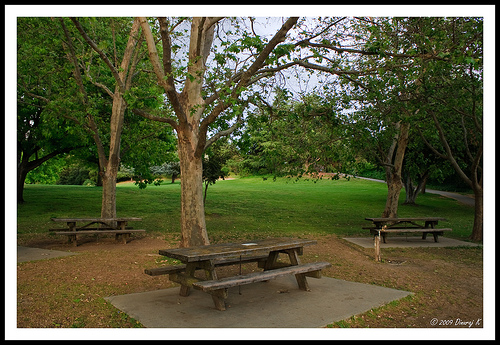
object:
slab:
[339, 233, 483, 251]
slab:
[99, 263, 418, 328]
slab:
[16, 242, 80, 269]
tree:
[52, 14, 190, 235]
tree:
[16, 15, 106, 203]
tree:
[358, 18, 474, 237]